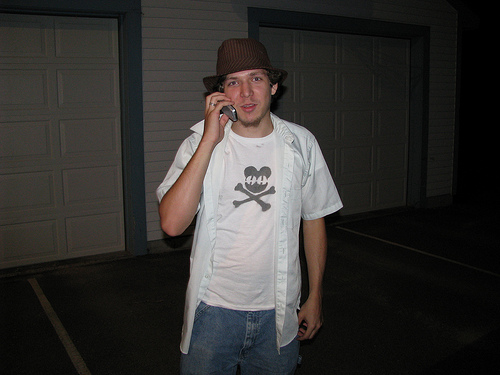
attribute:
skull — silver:
[242, 165, 271, 194]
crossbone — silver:
[232, 181, 276, 212]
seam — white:
[278, 148, 289, 335]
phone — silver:
[207, 89, 239, 123]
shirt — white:
[154, 110, 344, 355]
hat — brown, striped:
[200, 35, 288, 96]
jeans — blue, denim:
[180, 298, 303, 374]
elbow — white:
[158, 220, 180, 237]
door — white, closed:
[255, 23, 416, 224]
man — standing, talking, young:
[153, 37, 331, 370]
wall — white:
[142, 3, 252, 242]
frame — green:
[0, 0, 150, 254]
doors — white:
[1, 5, 421, 269]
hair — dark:
[204, 66, 287, 115]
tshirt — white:
[153, 106, 315, 315]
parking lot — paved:
[3, 198, 499, 374]